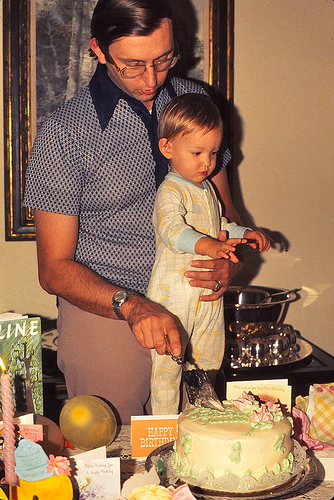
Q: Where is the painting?
A: Behind the man.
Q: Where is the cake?
A: Table.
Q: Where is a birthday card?
A: Table.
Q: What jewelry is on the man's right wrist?
A: Watch.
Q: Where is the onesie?
A: On the toddler.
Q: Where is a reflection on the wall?
A: Right of the serving bowl.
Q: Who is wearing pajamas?
A: Toddler.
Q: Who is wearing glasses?
A: Man in black and white shirt.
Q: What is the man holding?
A: A baby.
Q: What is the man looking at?
A: The cake.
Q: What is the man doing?
A: Cutting a cake.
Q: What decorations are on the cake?
A: Flowers.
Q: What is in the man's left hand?
A: A knife.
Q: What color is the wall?
A: Tan.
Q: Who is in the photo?
A: A guy and a baby.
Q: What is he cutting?
A: A cake.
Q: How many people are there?
A: Two.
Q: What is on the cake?
A: Frosting.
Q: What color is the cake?
A: White.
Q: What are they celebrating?
A: A birthday.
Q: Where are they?
A: At a party.